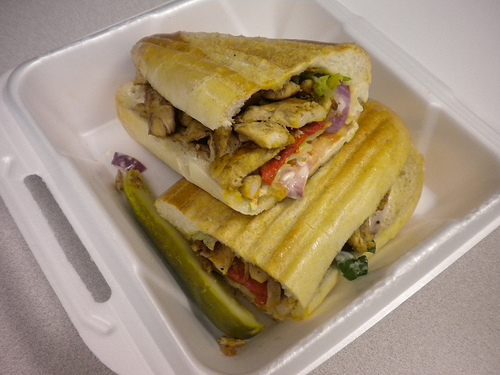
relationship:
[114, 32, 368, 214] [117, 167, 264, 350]
sandwich has pickle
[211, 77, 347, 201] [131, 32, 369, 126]
food between bread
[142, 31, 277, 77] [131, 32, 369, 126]
lines on bread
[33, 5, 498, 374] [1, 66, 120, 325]
box made of foam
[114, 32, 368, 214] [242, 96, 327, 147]
sandwich has meat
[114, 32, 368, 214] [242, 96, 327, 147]
sandwich has white meat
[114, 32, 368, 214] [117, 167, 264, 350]
sandwich by a pickle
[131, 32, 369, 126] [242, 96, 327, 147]
bread has meat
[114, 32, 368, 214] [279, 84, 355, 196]
sandwich has onion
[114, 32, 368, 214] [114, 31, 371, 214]
sandwich has a sandwich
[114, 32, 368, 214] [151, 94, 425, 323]
sandwich has a bottom half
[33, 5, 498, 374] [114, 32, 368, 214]
box has a sandwich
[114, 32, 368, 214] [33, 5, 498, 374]
sandwich in a box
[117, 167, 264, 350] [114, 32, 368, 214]
pickle beside a sandwich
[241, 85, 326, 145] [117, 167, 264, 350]
chicken with a pickle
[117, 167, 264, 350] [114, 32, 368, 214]
pickle by a sandwich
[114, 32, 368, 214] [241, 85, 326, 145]
sandwich has chicken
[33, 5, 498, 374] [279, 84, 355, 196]
box has onion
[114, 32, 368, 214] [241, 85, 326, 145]
sandwich with chicken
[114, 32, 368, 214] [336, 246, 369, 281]
sandwich with lettuce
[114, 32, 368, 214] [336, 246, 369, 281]
sandwich has lettuce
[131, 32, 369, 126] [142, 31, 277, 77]
bread has lines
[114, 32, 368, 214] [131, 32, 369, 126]
sandwich with italian bread